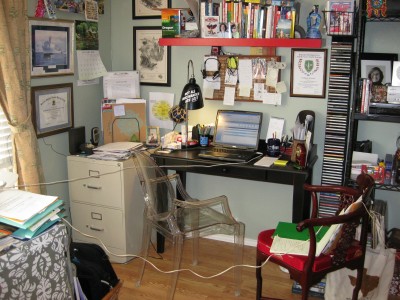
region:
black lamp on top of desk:
[175, 59, 203, 152]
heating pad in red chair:
[253, 174, 373, 298]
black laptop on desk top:
[192, 109, 265, 171]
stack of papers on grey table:
[2, 188, 67, 258]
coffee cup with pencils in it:
[266, 130, 284, 157]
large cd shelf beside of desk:
[294, 38, 355, 232]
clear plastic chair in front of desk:
[129, 146, 262, 294]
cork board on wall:
[200, 53, 284, 104]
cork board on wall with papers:
[201, 53, 289, 103]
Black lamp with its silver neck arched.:
[183, 58, 203, 150]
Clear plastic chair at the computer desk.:
[130, 148, 254, 297]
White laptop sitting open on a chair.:
[269, 222, 348, 257]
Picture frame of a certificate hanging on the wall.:
[28, 83, 79, 137]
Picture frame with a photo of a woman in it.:
[353, 52, 394, 109]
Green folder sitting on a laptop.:
[272, 222, 330, 244]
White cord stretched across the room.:
[56, 214, 324, 279]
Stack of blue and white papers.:
[0, 187, 69, 243]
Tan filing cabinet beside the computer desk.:
[67, 139, 153, 265]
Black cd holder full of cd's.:
[317, 30, 353, 223]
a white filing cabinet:
[64, 156, 141, 258]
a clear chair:
[133, 145, 246, 290]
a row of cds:
[320, 39, 349, 211]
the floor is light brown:
[89, 208, 293, 298]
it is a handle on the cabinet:
[83, 180, 102, 196]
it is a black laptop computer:
[204, 106, 265, 172]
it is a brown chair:
[258, 165, 371, 295]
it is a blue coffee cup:
[268, 137, 279, 157]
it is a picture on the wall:
[32, 85, 74, 134]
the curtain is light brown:
[2, 12, 47, 180]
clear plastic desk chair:
[126, 141, 244, 299]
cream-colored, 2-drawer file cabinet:
[66, 144, 157, 262]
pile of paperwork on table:
[1, 184, 67, 257]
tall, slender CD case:
[318, 35, 353, 226]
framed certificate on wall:
[31, 79, 76, 138]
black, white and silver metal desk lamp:
[176, 56, 205, 153]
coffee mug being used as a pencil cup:
[267, 135, 280, 155]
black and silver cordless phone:
[90, 123, 100, 145]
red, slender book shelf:
[157, 35, 323, 50]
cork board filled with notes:
[197, 50, 287, 110]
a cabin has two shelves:
[59, 136, 165, 270]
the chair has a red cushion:
[243, 177, 380, 298]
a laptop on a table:
[189, 95, 272, 179]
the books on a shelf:
[155, 1, 324, 55]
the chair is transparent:
[124, 143, 255, 299]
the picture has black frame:
[28, 21, 73, 73]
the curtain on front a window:
[1, 2, 51, 206]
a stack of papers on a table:
[0, 185, 73, 252]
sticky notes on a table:
[271, 152, 293, 174]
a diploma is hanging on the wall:
[30, 82, 75, 140]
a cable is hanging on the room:
[0, 157, 258, 189]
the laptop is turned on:
[196, 106, 262, 166]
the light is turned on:
[178, 58, 204, 151]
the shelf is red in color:
[155, 36, 322, 49]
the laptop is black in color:
[200, 107, 264, 167]